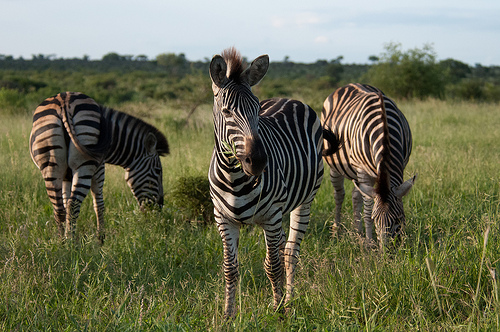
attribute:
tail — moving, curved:
[59, 96, 103, 162]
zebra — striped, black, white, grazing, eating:
[28, 90, 171, 242]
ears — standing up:
[208, 53, 271, 88]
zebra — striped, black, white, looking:
[203, 47, 339, 318]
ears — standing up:
[349, 174, 415, 196]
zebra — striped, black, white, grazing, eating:
[321, 81, 416, 253]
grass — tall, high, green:
[0, 96, 498, 330]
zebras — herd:
[29, 47, 414, 315]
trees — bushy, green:
[1, 42, 499, 99]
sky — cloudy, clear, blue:
[1, 0, 499, 68]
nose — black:
[244, 151, 268, 169]